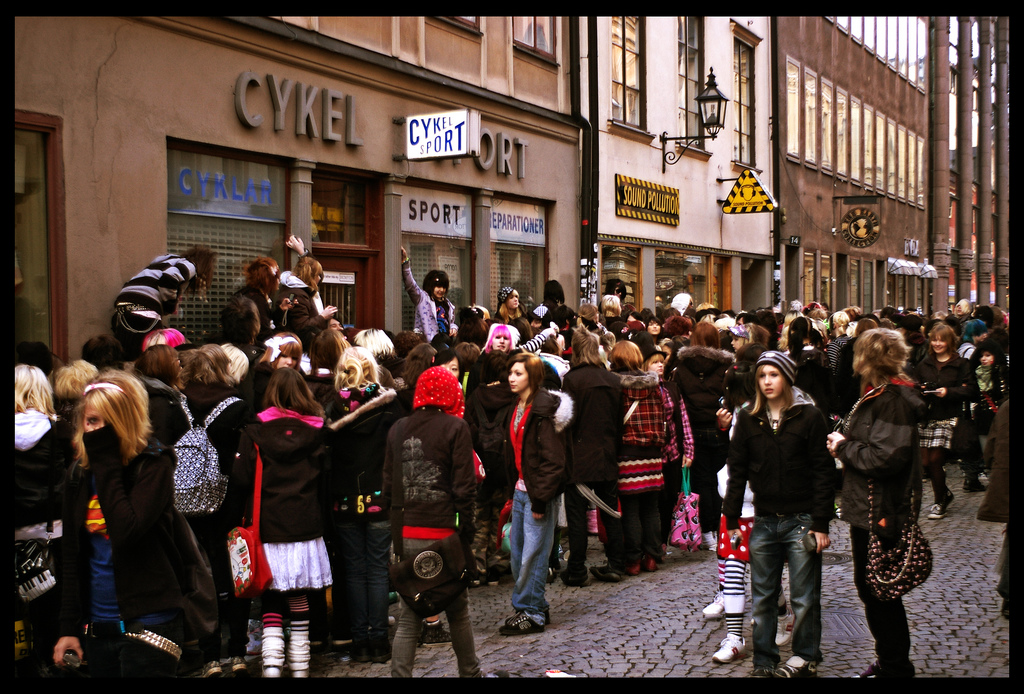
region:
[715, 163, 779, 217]
A yellow triangle sign with black marks on it.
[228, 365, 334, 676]
Brown haired girl in a white skirt and high socks.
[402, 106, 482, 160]
White sign that says CYKEL SPORT.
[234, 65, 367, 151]
The word CYKEL in grey letters on a brown building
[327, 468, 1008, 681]
A brown bricked road.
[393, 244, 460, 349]
Black haired girl standing under the word SPORT in a window.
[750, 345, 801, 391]
Black and white striped hat on a girl.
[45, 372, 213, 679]
Blonde girl with pink headband walking away from the crowd in a blue shirt.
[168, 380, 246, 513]
A black and white backpack.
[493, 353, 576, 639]
Brown haired girl in a brown parka with white fur hood in jeans and black shoes.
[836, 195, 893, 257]
sign hanging on the building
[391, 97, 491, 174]
sign hanging on the building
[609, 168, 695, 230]
sign hanging on the building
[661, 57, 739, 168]
light hanging on the wall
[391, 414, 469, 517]
woman wearing a black jacket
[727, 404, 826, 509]
woman wearing a black jacket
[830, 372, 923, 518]
woman wearing a black jacket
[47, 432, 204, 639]
woman wearing a black jacket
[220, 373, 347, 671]
the person is standing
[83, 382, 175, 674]
the person is standing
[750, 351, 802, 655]
the person is standing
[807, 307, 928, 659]
the person is standing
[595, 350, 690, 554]
the person is standing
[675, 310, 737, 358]
the person is standing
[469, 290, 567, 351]
the person is standing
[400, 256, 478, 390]
the person is standing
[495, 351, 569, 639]
person walking on cobble street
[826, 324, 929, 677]
person walking on cobble street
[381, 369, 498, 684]
person walking on cobble street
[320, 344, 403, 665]
person walking on cobble street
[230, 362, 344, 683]
person walking on cobble street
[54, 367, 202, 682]
person walking on cobble street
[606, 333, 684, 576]
person walking on cobble street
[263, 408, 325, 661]
the person is standing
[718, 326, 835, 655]
the person is standing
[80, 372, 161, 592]
the person is standing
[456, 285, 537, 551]
the person is standing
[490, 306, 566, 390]
the person is standing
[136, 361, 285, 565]
the person is standing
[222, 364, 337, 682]
person holding a red bag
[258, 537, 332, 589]
the skirt is white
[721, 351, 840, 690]
the young person is wearing a hat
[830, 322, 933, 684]
the person is carrying a bag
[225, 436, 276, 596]
the bag is red and white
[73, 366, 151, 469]
the hair is straight and blonde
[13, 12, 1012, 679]
the people gathered in the city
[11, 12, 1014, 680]
the large group of people near the building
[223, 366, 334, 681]
the girl wearing the white skirt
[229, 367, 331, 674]
the girl carrying the red and white bag